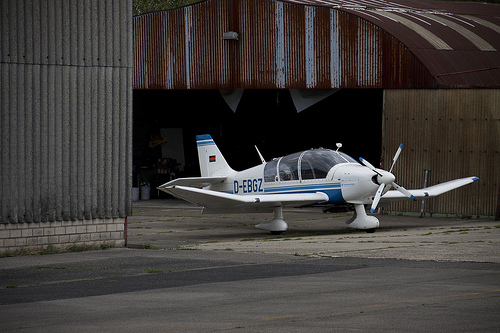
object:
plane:
[156, 134, 480, 236]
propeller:
[359, 144, 415, 214]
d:
[233, 180, 239, 194]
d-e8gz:
[233, 177, 263, 193]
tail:
[196, 134, 238, 177]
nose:
[377, 171, 397, 186]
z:
[258, 178, 263, 192]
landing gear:
[255, 204, 380, 236]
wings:
[158, 175, 478, 210]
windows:
[264, 147, 361, 183]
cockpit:
[261, 147, 361, 193]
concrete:
[0, 248, 500, 333]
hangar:
[2, 4, 499, 234]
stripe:
[263, 182, 341, 195]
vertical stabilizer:
[159, 176, 227, 189]